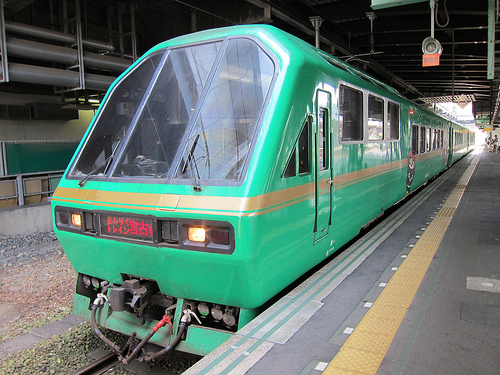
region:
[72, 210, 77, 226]
The left yellow light on the front of the train.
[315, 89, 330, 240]
The door on the right side of the train.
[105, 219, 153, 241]
The red Asian letters on the front of the train.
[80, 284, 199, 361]
The wires on the front of the train.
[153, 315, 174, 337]
The red grip on the tube on the front of the train.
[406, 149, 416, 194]
The design on the side of the train.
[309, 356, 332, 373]
small white square on platform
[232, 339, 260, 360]
blue and white color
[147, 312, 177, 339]
small red hose on front of train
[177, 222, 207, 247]
small bright yellow light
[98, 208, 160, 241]
oriental words on front of train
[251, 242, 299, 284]
green color on train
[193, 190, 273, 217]
gold border around the train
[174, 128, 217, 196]
tall wind shield wiper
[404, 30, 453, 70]
flood light in the ceiling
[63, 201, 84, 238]
a light on a train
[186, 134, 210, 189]
wipers on the train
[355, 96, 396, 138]
a window on a train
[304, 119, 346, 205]
a door on a train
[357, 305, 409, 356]
a yellow line on the ground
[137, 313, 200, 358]
hoses on the front of the train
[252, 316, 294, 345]
green stripes on the ground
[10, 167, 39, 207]
railing against the wall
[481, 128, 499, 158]
people waiting on the train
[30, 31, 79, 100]
pipes on the wall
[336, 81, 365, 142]
window on side of train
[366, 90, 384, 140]
window on side of train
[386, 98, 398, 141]
window on side of train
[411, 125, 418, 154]
window on side of train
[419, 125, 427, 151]
window on side of train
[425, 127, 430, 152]
window on side of train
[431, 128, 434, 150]
window on side of train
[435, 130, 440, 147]
window on side of train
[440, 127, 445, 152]
window on side of train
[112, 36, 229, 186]
window on front of train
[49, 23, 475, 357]
Train is green with gold stripe.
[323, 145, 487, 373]
Stripe is yellow.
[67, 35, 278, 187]
Windshield of train.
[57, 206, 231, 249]
Headlight of train.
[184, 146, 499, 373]
Platform near train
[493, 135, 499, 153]
Person standing on platform.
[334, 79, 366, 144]
Small window on side of train.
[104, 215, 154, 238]
Red foriegn writing on bus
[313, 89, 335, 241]
door on side of train.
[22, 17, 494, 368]
train moving down tracks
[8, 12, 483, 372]
the train has three windows in front